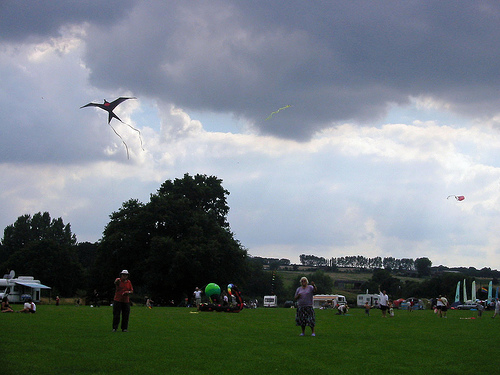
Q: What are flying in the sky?
A: Kites.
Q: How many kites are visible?
A: Three.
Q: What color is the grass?
A: Green.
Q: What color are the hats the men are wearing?
A: White.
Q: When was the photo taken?
A: Daytime.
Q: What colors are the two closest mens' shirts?
A: Red and purple.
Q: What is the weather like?
A: Cloudy.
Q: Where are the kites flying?
A: In the sky.